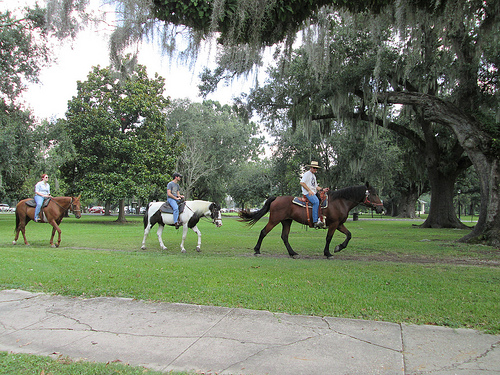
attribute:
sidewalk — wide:
[70, 287, 316, 374]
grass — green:
[203, 258, 436, 311]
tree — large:
[373, 6, 495, 250]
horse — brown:
[11, 194, 94, 254]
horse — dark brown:
[252, 180, 388, 268]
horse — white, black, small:
[138, 195, 229, 257]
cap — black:
[172, 168, 186, 181]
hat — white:
[300, 156, 325, 170]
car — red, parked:
[86, 202, 110, 219]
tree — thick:
[424, 180, 467, 228]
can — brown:
[350, 212, 368, 222]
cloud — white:
[52, 63, 76, 101]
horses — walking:
[6, 182, 390, 260]